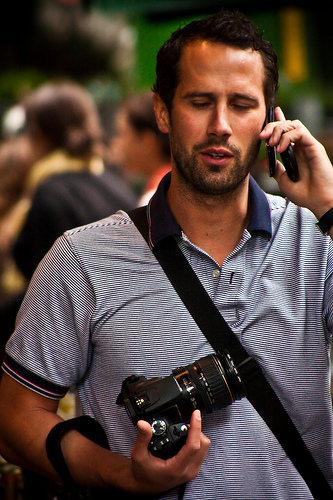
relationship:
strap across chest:
[126, 201, 322, 492] [85, 208, 318, 490]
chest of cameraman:
[85, 208, 318, 490] [0, 13, 333, 494]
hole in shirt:
[226, 270, 236, 285] [6, 198, 321, 495]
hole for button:
[226, 270, 236, 285] [208, 266, 223, 281]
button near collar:
[210, 267, 219, 278] [145, 161, 271, 250]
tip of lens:
[215, 345, 248, 395] [176, 351, 250, 414]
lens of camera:
[176, 351, 250, 414] [114, 349, 244, 460]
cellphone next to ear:
[265, 104, 297, 179] [264, 95, 276, 116]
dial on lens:
[189, 360, 221, 410] [174, 347, 247, 416]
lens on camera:
[176, 351, 250, 414] [114, 349, 244, 460]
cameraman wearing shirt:
[0, 13, 333, 494] [17, 176, 322, 489]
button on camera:
[149, 417, 168, 432] [114, 349, 244, 460]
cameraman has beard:
[0, 13, 333, 494] [167, 124, 259, 191]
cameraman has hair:
[0, 13, 333, 494] [150, 10, 279, 114]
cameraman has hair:
[0, 13, 333, 494] [154, 16, 282, 105]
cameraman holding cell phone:
[0, 13, 333, 494] [264, 103, 296, 182]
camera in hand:
[112, 349, 252, 453] [120, 413, 210, 489]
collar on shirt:
[144, 171, 182, 245] [17, 176, 322, 489]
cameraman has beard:
[0, 13, 333, 494] [170, 135, 259, 206]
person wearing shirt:
[6, 84, 136, 291] [5, 168, 139, 257]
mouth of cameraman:
[200, 146, 232, 166] [9, 19, 320, 495]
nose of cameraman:
[205, 98, 231, 137] [9, 19, 320, 495]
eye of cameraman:
[189, 98, 211, 108] [9, 19, 320, 495]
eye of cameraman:
[232, 99, 257, 110] [9, 19, 320, 495]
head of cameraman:
[148, 16, 283, 204] [9, 19, 320, 495]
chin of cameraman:
[198, 168, 234, 185] [9, 19, 320, 495]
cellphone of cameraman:
[266, 104, 277, 179] [9, 19, 320, 495]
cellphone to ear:
[266, 104, 277, 179] [265, 87, 277, 136]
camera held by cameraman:
[115, 347, 249, 460] [9, 19, 320, 495]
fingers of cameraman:
[173, 408, 214, 480] [9, 19, 320, 495]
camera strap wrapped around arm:
[43, 413, 114, 498] [1, 235, 140, 497]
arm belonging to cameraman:
[1, 235, 140, 497] [0, 13, 333, 494]